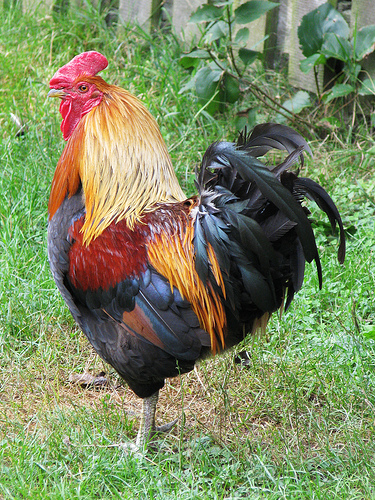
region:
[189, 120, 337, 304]
the black tail feathers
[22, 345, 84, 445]
brown patch in the grass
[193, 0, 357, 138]
weeds near the fence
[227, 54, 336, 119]
the branches with leaves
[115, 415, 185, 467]
talons of the chicken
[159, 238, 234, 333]
oragne feather on the side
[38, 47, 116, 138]
the red head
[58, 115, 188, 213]
the orange and red neck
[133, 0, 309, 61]
the wooden picket fence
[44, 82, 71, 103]
the beak of the bird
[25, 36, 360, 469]
rooster is on a field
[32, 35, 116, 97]
rooster has red crest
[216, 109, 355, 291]
feathers of tail of rooster are black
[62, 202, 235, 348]
wings of rooster are color red, yellow and black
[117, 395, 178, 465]
legs of rooster are tan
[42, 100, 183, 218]
feathers are yellow and orange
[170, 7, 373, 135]
a green plant next to a fence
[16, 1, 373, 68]
fence is made of wood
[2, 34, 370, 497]
rooster stand on a green field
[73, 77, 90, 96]
eye of rooster is brown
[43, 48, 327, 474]
the rooster standing in the yard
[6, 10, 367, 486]
the green grass on the ground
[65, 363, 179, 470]
the feet of the roosters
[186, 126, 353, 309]
the black tail feathers of the rooster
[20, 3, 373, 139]
the wooden fence next to the rooster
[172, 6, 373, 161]
the green leafy plant next to the fence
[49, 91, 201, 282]
the bright feathers on the rooster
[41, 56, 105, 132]
the head on the rooster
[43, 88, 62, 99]
the rooster beak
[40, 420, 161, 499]
some green grass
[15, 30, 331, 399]
Rooster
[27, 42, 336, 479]
The rooster is standing in the grass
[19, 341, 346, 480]
The grass is brown and green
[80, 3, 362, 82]
Yard is enclosed by a fence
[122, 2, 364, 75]
The fence is made of wood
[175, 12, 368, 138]
Weeds growing out of the ground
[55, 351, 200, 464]
Both of the rooster's feet are on the ground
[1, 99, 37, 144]
Isolated feather in the grass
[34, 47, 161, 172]
Picture of rooster in profile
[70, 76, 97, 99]
Rooster's eye is open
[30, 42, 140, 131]
Rooster with a red head.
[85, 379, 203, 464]
Foot on the rooster.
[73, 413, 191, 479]
Grass on the ground.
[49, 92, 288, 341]
Colorful feathers on the rooster.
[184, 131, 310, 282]
Dark feathers on the rooster.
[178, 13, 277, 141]
Leaves on the plants.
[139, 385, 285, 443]
Dirt on the grass.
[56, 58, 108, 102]
Eye of the rooster.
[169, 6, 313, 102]
Fence in the background.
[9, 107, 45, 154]
Leaf in the grass.